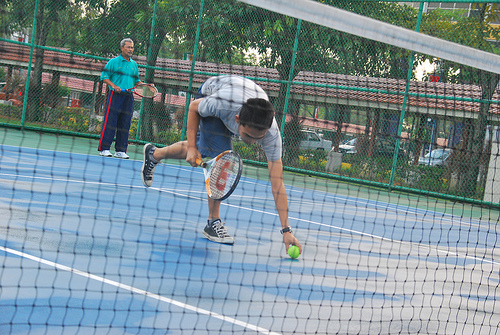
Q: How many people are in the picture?
A: Two.